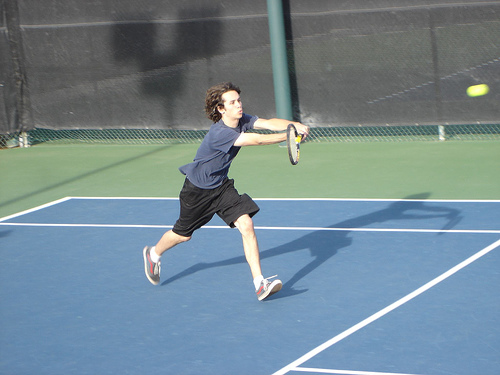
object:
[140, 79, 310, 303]
man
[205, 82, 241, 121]
hair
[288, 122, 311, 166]
tennis racket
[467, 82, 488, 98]
tennis ball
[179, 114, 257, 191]
t-shirt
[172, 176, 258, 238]
shorts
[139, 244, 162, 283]
athletic shoe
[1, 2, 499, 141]
net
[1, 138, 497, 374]
ground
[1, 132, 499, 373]
tennis court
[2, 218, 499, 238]
line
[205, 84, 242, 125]
head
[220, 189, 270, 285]
leg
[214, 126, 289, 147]
arm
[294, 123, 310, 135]
hand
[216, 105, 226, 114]
ear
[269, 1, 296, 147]
pole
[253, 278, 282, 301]
athletic shoe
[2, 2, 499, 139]
fence